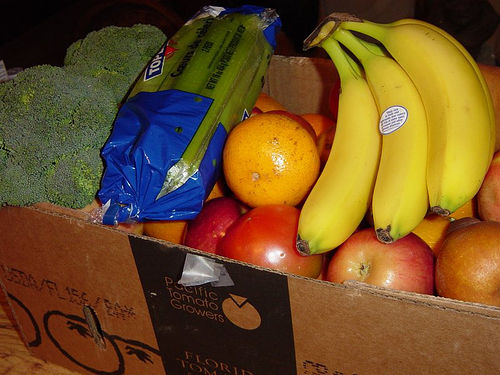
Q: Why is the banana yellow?
A: Its fresh.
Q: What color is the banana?
A: Yellow.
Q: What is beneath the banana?
A: Apples.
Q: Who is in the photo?
A: No one.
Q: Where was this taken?
A: A farmer's market.